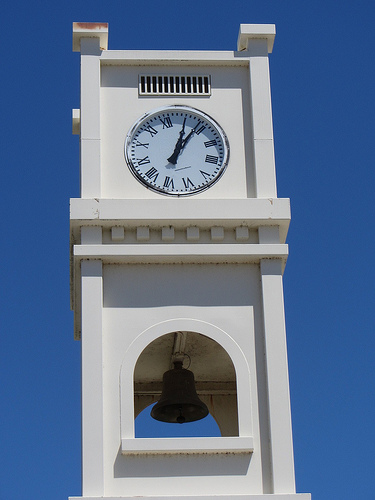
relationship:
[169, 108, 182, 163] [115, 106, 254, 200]
hands of a clock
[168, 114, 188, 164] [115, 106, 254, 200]
hands of a clock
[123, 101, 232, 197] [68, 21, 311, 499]
clock on bell tower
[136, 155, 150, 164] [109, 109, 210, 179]
numeral on clock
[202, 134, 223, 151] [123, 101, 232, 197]
numeral on clock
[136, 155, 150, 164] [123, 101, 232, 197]
numeral on clock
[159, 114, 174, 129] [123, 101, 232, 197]
roman numeral on clock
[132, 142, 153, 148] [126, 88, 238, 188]
numeral on clock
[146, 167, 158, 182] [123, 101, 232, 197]
roman numeral on clock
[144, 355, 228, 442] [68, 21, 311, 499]
bell on bell tower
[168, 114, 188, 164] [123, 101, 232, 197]
hands on clock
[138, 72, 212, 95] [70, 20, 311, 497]
grate in tower